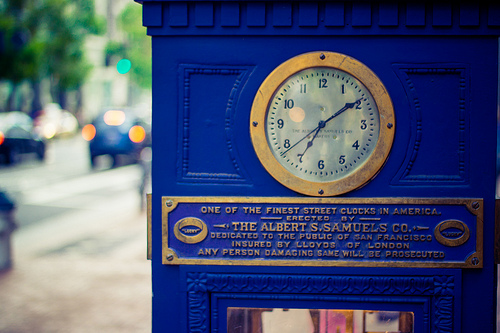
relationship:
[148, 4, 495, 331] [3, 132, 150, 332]
object near street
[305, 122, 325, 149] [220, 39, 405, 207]
hand on clock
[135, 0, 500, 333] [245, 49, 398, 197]
object under clock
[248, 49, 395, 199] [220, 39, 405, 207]
rim around clock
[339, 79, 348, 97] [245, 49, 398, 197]
number on clock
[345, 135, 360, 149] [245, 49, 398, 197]
number on clock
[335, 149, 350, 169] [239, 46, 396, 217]
number on clock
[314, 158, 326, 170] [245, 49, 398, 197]
number on clock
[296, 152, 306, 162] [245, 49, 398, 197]
number on clock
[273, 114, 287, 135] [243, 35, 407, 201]
number on clock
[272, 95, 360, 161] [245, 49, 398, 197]
hands on clock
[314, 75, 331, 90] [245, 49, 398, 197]
number on clock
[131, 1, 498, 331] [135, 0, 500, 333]
clock on object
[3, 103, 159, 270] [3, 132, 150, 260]
cars on street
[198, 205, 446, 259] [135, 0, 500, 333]
words on object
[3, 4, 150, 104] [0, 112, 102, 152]
trees on sidewalk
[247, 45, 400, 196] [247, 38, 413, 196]
trim on clock